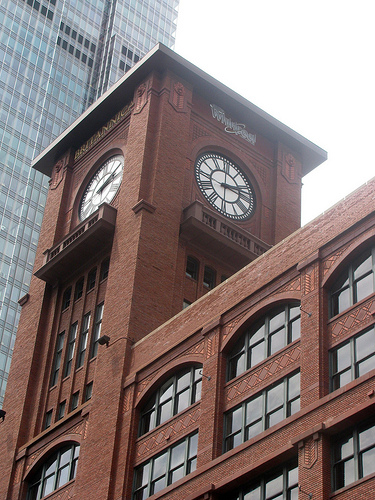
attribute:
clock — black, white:
[192, 144, 259, 225]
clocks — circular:
[69, 136, 263, 228]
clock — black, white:
[76, 163, 129, 212]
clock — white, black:
[193, 140, 261, 217]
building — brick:
[6, 40, 370, 496]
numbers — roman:
[195, 148, 256, 221]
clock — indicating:
[195, 128, 268, 224]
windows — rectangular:
[82, 312, 107, 332]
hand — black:
[220, 178, 258, 197]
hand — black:
[223, 185, 250, 202]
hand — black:
[98, 164, 121, 183]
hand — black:
[94, 171, 120, 194]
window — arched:
[122, 364, 213, 490]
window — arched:
[220, 280, 310, 459]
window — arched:
[318, 252, 364, 397]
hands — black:
[97, 163, 124, 177]